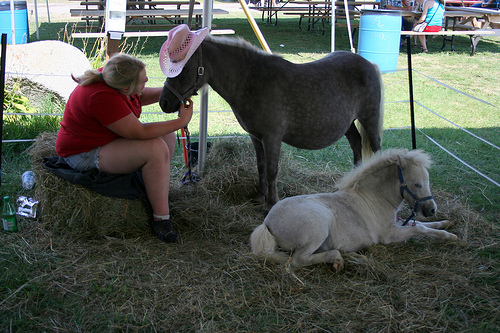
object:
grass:
[80, 246, 498, 308]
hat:
[159, 24, 208, 78]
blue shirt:
[425, 2, 446, 26]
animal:
[159, 34, 384, 214]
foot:
[151, 209, 178, 243]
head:
[400, 156, 437, 218]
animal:
[250, 148, 457, 272]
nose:
[417, 200, 437, 217]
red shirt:
[56, 67, 142, 159]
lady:
[54, 54, 192, 244]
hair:
[204, 31, 284, 59]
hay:
[115, 248, 253, 327]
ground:
[0, 0, 499, 332]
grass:
[393, 58, 496, 149]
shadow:
[437, 131, 498, 215]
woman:
[401, 0, 445, 52]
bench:
[401, 31, 496, 57]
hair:
[71, 53, 146, 95]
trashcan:
[357, 8, 403, 73]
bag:
[361, 9, 402, 14]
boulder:
[3, 40, 91, 113]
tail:
[356, 63, 385, 166]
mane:
[334, 145, 434, 190]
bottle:
[1, 195, 17, 231]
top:
[3, 195, 9, 201]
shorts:
[63, 146, 101, 171]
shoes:
[146, 214, 178, 243]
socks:
[153, 214, 170, 222]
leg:
[259, 135, 282, 219]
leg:
[343, 121, 361, 171]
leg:
[358, 103, 384, 157]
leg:
[290, 230, 344, 273]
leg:
[382, 223, 458, 244]